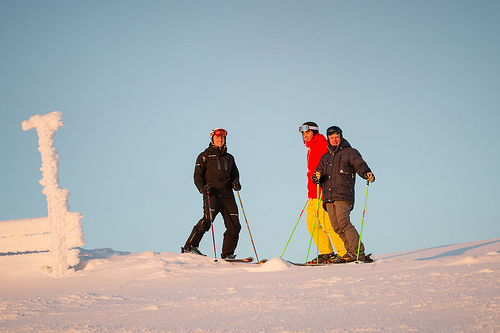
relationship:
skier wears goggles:
[294, 111, 340, 274] [294, 122, 319, 135]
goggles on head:
[294, 122, 319, 135] [291, 120, 321, 147]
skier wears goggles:
[179, 123, 262, 263] [204, 128, 233, 138]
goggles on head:
[204, 128, 233, 138] [208, 122, 230, 152]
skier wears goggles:
[314, 127, 381, 272] [323, 125, 347, 136]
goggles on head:
[323, 125, 347, 136] [321, 128, 350, 152]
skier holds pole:
[179, 123, 262, 263] [233, 182, 271, 271]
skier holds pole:
[179, 123, 262, 263] [200, 188, 229, 273]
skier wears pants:
[294, 111, 340, 274] [303, 188, 349, 270]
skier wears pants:
[314, 127, 381, 272] [323, 198, 381, 269]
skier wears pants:
[179, 123, 262, 263] [191, 184, 251, 263]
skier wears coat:
[294, 111, 340, 274] [302, 135, 331, 202]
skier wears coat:
[314, 127, 381, 272] [310, 144, 379, 209]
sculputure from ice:
[19, 106, 108, 274] [17, 216, 85, 270]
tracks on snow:
[289, 275, 368, 300] [1, 225, 499, 332]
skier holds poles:
[294, 111, 340, 274] [278, 187, 326, 275]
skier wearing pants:
[294, 111, 340, 274] [303, 188, 349, 270]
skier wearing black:
[179, 123, 262, 263] [186, 147, 245, 258]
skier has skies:
[294, 111, 340, 274] [286, 254, 338, 267]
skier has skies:
[179, 123, 262, 263] [191, 248, 272, 271]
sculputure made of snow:
[19, 106, 108, 274] [1, 225, 499, 332]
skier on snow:
[184, 128, 241, 259] [1, 225, 499, 332]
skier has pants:
[294, 111, 340, 274] [303, 188, 349, 270]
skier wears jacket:
[179, 123, 262, 263] [196, 144, 242, 198]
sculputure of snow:
[19, 106, 108, 274] [1, 225, 499, 332]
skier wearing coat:
[294, 111, 340, 274] [302, 135, 331, 202]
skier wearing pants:
[314, 127, 381, 272] [323, 198, 381, 269]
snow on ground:
[1, 225, 499, 332] [26, 276, 497, 330]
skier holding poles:
[294, 111, 340, 274] [278, 187, 326, 275]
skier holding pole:
[179, 123, 262, 263] [236, 191, 259, 263]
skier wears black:
[179, 123, 262, 263] [186, 147, 245, 258]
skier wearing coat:
[314, 127, 381, 272] [310, 144, 379, 209]